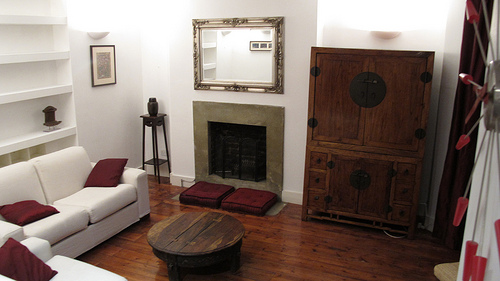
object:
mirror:
[191, 16, 285, 94]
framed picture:
[89, 44, 117, 86]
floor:
[259, 237, 404, 280]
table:
[146, 211, 247, 281]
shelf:
[0, 12, 79, 169]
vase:
[147, 97, 159, 117]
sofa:
[0, 144, 154, 259]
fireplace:
[206, 121, 268, 184]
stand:
[139, 113, 172, 185]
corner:
[129, 1, 154, 177]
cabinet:
[301, 45, 436, 241]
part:
[209, 122, 221, 130]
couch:
[0, 146, 152, 281]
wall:
[317, 0, 467, 51]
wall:
[68, 1, 145, 172]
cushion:
[53, 182, 138, 224]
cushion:
[22, 208, 90, 246]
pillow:
[85, 158, 130, 188]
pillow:
[0, 199, 61, 226]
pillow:
[0, 237, 58, 281]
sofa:
[0, 236, 129, 281]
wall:
[138, 0, 318, 205]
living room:
[0, 0, 500, 281]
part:
[113, 98, 128, 135]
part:
[148, 120, 153, 125]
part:
[78, 187, 118, 222]